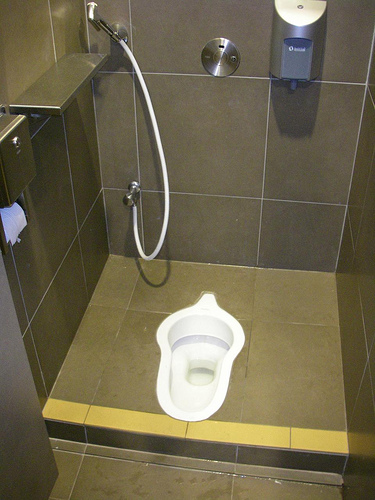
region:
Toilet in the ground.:
[112, 259, 258, 450]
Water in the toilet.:
[162, 338, 268, 423]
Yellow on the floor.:
[81, 393, 345, 474]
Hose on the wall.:
[80, 2, 216, 290]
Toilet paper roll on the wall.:
[1, 107, 63, 273]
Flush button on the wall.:
[170, 15, 281, 114]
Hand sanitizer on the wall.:
[262, 1, 360, 105]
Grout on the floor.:
[77, 439, 158, 495]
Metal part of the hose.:
[106, 161, 153, 221]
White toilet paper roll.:
[0, 208, 49, 252]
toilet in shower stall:
[152, 289, 248, 421]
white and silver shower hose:
[83, 2, 173, 266]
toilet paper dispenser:
[2, 195, 33, 243]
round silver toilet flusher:
[198, 37, 246, 81]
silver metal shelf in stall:
[9, 51, 115, 114]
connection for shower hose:
[121, 178, 146, 213]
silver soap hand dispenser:
[265, 0, 331, 96]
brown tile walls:
[169, 77, 360, 283]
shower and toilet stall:
[2, 2, 349, 456]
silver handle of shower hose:
[79, 0, 133, 52]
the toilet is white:
[137, 280, 239, 423]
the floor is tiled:
[81, 250, 333, 441]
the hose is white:
[117, 46, 194, 317]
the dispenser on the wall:
[261, 12, 354, 160]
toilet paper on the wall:
[1, 122, 58, 297]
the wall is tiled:
[155, 44, 296, 309]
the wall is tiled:
[321, 168, 370, 396]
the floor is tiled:
[111, 451, 272, 498]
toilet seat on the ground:
[135, 284, 311, 483]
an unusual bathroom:
[2, 5, 367, 488]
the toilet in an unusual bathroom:
[151, 277, 249, 433]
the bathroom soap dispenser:
[251, 0, 341, 94]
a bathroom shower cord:
[80, 0, 193, 267]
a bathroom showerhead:
[63, 0, 131, 49]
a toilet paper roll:
[0, 200, 28, 245]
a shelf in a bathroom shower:
[13, 22, 108, 133]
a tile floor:
[105, 249, 335, 376]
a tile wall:
[186, 95, 338, 249]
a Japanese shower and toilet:
[0, 1, 373, 474]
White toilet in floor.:
[165, 285, 261, 398]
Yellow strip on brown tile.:
[45, 378, 285, 448]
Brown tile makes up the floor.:
[96, 457, 197, 496]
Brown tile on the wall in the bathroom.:
[190, 120, 323, 233]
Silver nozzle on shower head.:
[77, 8, 127, 47]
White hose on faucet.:
[114, 38, 176, 178]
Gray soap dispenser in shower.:
[272, 25, 349, 123]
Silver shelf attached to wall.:
[14, 43, 83, 102]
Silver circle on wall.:
[199, 39, 264, 88]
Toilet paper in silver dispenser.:
[2, 197, 25, 252]